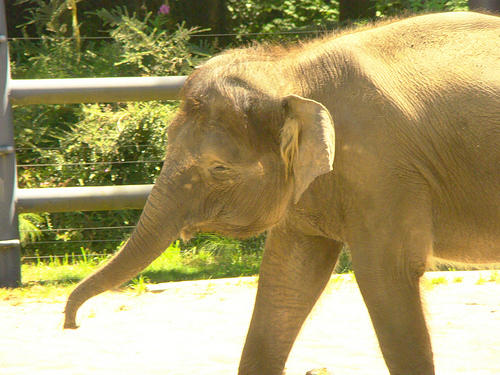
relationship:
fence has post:
[0, 3, 184, 288] [0, 2, 23, 291]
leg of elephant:
[342, 210, 449, 372] [62, 11, 499, 373]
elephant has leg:
[62, 11, 499, 373] [354, 234, 451, 374]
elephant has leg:
[62, 11, 499, 373] [240, 228, 348, 373]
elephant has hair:
[62, 11, 499, 373] [248, 41, 283, 62]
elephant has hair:
[62, 11, 499, 373] [238, 16, 404, 57]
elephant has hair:
[27, 10, 467, 374] [220, 31, 311, 60]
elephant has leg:
[62, 11, 499, 373] [348, 238, 435, 373]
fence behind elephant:
[23, 74, 115, 206] [127, 62, 488, 367]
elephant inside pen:
[62, 11, 499, 373] [0, 38, 499, 287]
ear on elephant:
[283, 92, 336, 211] [62, 11, 499, 373]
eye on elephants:
[205, 161, 236, 178] [203, 63, 402, 240]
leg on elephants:
[231, 222, 350, 373] [59, 25, 488, 374]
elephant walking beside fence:
[62, 11, 499, 373] [0, 3, 184, 288]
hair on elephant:
[223, 23, 369, 69] [62, 11, 499, 373]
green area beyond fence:
[5, 2, 468, 291] [0, 3, 184, 288]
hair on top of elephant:
[240, 47, 308, 84] [115, 0, 495, 318]